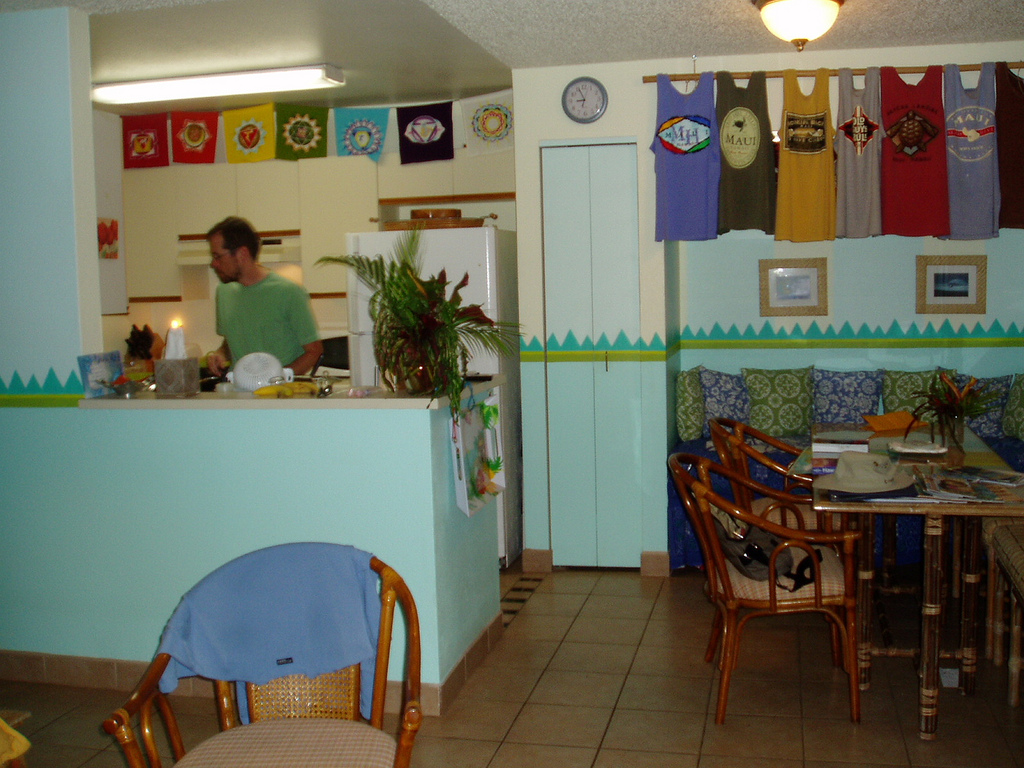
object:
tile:
[520, 704, 621, 740]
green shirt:
[206, 279, 323, 357]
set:
[662, 409, 889, 723]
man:
[198, 211, 322, 372]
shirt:
[205, 271, 315, 375]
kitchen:
[5, 0, 539, 714]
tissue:
[153, 325, 198, 361]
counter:
[0, 375, 507, 715]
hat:
[814, 448, 916, 494]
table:
[805, 419, 1019, 739]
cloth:
[158, 544, 377, 720]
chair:
[99, 538, 422, 762]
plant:
[310, 219, 508, 417]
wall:
[515, 38, 1022, 576]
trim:
[515, 315, 1022, 358]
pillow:
[699, 367, 743, 420]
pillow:
[740, 358, 819, 443]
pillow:
[818, 367, 887, 426]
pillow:
[881, 369, 936, 417]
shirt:
[143, 539, 382, 717]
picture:
[451, 388, 509, 516]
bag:
[712, 507, 825, 594]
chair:
[666, 444, 868, 728]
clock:
[556, 70, 614, 131]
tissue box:
[150, 353, 202, 400]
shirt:
[644, 70, 724, 245]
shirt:
[712, 70, 780, 235]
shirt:
[777, 66, 842, 242]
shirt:
[830, 61, 884, 239]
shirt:
[876, 64, 950, 240]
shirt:
[937, 56, 1002, 245]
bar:
[636, 57, 1024, 88]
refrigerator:
[343, 220, 521, 573]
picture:
[755, 252, 831, 322]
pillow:
[673, 362, 706, 444]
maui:
[655, 112, 718, 156]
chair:
[709, 414, 818, 490]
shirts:
[992, 67, 1024, 220]